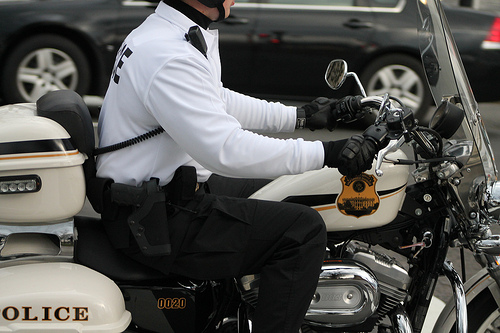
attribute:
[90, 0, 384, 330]
officer — police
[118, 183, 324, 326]
pants — black, colored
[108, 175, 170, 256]
gun — protection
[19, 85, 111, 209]
seat — in back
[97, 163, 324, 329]
pants — black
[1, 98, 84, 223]
storage — back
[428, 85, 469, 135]
speedometer — motorcycle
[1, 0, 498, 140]
car — back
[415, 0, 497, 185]
protective shield — bullet proof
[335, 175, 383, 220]
badge emblem — yellow, black, police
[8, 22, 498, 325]
motorcycle — black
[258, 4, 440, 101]
car — black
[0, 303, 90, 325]
word — black, yellow, police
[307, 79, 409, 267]
emblem — black , yellow 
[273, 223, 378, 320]
engine — silver 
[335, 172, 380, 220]
emblem — for police ,  Yellow , of  White House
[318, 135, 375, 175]
riding glove — black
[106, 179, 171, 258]
gun holster — black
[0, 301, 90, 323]
word — police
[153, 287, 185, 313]
number — bike 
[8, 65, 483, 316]
motorcycle — shiny, silver